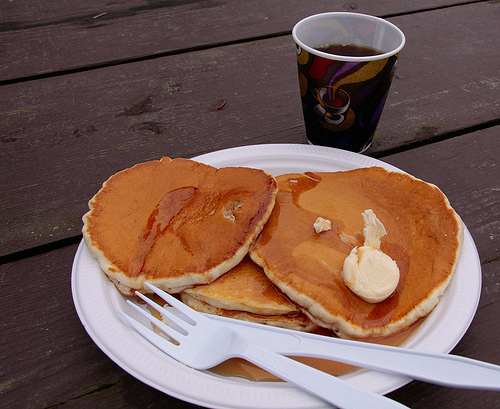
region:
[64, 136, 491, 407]
pancakes on a plate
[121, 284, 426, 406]
a fork on a plate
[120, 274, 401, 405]
the fork is plastic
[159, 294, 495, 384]
a knife under the fork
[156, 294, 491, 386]
the knife is white plastic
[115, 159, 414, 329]
syrup running off the pancakes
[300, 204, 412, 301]
butter sliding off the pancake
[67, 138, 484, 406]
the plate is round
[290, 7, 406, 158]
a cup behind the plate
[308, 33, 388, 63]
coffee in the cup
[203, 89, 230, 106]
tiny brown stem on table top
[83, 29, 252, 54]
lines on the table top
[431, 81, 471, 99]
chipped paint on the table top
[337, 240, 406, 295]
pat of butter on top of pancakes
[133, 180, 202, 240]
maple syrup drizzled over pancakes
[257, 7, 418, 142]
colorful coffeee cup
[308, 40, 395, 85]
black coffee in coffee cup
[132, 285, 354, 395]
white plastic fork and knife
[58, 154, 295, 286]
flat brown pancake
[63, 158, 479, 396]
white plate filled with pancakes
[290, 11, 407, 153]
a small cup with a design on it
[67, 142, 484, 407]
white paper plate with pancakes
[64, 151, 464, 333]
four round pancakes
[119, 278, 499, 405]
plastic fork and knife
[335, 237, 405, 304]
round piece of butter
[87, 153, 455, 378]
syrup on top the pancakes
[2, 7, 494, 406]
breakfast sitting on a wood table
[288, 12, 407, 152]
picture of a coffee cup on the cup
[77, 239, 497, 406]
fork and knife on a paper plate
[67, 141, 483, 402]
plate of pancakes with syrup and butter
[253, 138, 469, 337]
a pan cake covered in butter.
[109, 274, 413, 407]
a white plastic fork.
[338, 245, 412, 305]
a dab of butter.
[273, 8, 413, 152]
a cup of coffee on a table.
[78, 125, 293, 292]
a pancake on a white plate.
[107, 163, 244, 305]
syrup on a pancake.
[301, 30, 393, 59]
coffee inside of a cup.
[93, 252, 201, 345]
prongs on a white fork.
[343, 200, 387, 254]
a streak of melted butter.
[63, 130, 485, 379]
a plate of food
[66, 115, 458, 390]
the plate is white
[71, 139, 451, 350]
pancakes are on the plate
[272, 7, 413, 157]
a cup on the table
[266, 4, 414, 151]
coffee is in the cup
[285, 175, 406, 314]
a ball of butter on the pancakes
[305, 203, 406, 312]
the butter is yellow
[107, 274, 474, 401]
knife and fork on the plate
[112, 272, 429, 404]
the fork and knife are plastic